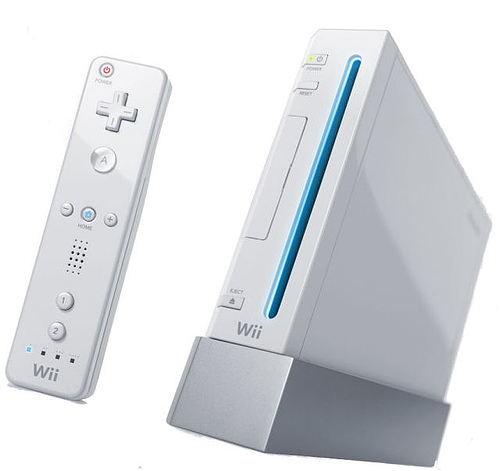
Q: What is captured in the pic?
A: A WII console and remote.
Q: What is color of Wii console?
A: White.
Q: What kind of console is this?
A: A Wii console.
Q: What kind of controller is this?
A: A Wii controller.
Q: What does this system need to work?
A: A television.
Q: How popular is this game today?
A: Very popular.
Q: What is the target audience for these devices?
A: Teenage boys.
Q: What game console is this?
A: Nintendo Wii.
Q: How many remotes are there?
A: One.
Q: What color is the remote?
A: White.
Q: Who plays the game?
A: Boys and girls.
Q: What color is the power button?
A: Red.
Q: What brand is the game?
A: Wii.